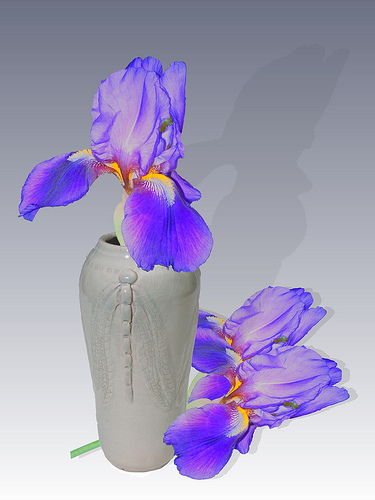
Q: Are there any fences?
A: No, there are no fences.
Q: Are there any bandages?
A: No, there are no bandages.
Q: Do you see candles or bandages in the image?
A: No, there are no bandages or candles.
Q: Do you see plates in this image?
A: No, there are no plates.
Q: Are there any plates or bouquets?
A: No, there are no plates or bouquets.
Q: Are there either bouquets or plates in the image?
A: No, there are no plates or bouquets.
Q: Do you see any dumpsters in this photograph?
A: No, there are no dumpsters.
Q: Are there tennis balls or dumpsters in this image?
A: No, there are no dumpsters or tennis balls.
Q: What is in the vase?
A: The flower is in the vase.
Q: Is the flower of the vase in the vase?
A: Yes, the flower is in the vase.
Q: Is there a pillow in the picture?
A: No, there are no pillows.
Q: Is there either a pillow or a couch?
A: No, there are no pillows or couches.